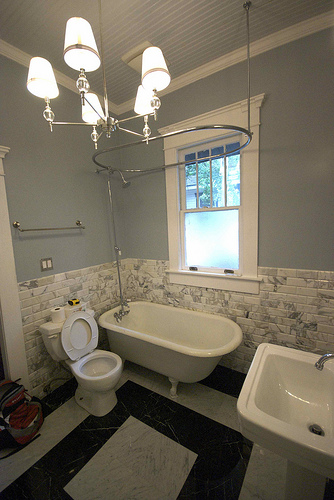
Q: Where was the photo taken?
A: It was taken at the bathroom.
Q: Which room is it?
A: It is a bathroom.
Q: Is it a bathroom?
A: Yes, it is a bathroom.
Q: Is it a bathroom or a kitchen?
A: It is a bathroom.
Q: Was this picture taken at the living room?
A: No, the picture was taken in the bathroom.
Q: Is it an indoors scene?
A: Yes, it is indoors.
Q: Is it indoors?
A: Yes, it is indoors.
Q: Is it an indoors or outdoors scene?
A: It is indoors.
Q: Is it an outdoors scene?
A: No, it is indoors.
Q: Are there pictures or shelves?
A: No, there are no shelves or pictures.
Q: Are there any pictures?
A: No, there are no pictures.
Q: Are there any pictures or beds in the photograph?
A: No, there are no pictures or beds.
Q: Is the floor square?
A: Yes, the floor is square.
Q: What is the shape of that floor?
A: The floor is square.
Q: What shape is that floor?
A: The floor is square.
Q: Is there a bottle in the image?
A: No, there are no bottles.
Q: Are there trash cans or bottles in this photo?
A: No, there are no bottles or trash cans.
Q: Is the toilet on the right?
A: No, the toilet is on the left of the image.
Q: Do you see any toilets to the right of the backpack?
A: Yes, there is a toilet to the right of the backpack.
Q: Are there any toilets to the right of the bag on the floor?
A: Yes, there is a toilet to the right of the backpack.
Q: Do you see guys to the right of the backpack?
A: No, there is a toilet to the right of the backpack.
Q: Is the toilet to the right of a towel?
A: No, the toilet is to the right of a backpack.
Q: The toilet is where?
A: The toilet is in the bathroom.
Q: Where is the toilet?
A: The toilet is in the bathroom.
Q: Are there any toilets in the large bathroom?
A: Yes, there is a toilet in the bathroom.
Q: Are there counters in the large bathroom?
A: No, there is a toilet in the bathroom.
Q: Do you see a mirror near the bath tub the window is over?
A: No, there is a toilet near the bath tub.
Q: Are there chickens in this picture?
A: No, there are no chickens.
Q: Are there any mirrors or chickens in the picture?
A: No, there are no chickens or mirrors.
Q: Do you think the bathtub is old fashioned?
A: Yes, the bathtub is old fashioned.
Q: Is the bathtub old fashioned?
A: Yes, the bathtub is old fashioned.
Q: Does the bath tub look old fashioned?
A: Yes, the bath tub is old fashioned.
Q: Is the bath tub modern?
A: No, the bath tub is old fashioned.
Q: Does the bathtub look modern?
A: No, the bathtub is old fashioned.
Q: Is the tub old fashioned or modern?
A: The tub is old fashioned.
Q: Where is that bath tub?
A: The bath tub is in the bathroom.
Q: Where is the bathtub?
A: The bath tub is in the bathroom.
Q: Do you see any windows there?
A: Yes, there is a window.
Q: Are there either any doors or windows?
A: Yes, there is a window.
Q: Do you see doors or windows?
A: Yes, there is a window.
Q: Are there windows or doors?
A: Yes, there is a window.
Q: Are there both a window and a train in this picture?
A: No, there is a window but no trains.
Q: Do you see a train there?
A: No, there are no trains.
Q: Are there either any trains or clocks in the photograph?
A: No, there are no trains or clocks.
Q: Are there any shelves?
A: No, there are no shelves.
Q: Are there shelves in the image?
A: No, there are no shelves.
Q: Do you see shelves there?
A: No, there are no shelves.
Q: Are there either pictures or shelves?
A: No, there are no shelves or pictures.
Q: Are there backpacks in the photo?
A: Yes, there is a backpack.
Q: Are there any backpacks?
A: Yes, there is a backpack.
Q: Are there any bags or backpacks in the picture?
A: Yes, there is a backpack.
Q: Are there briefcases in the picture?
A: No, there are no briefcases.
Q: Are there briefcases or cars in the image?
A: No, there are no briefcases or cars.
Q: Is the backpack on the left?
A: Yes, the backpack is on the left of the image.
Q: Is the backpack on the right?
A: No, the backpack is on the left of the image.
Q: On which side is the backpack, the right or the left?
A: The backpack is on the left of the image.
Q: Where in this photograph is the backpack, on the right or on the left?
A: The backpack is on the left of the image.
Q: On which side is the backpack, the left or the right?
A: The backpack is on the left of the image.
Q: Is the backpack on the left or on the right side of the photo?
A: The backpack is on the left of the image.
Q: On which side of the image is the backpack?
A: The backpack is on the left of the image.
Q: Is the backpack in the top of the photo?
A: No, the backpack is in the bottom of the image.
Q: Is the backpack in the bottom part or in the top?
A: The backpack is in the bottom of the image.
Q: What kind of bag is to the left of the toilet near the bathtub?
A: The bag is a backpack.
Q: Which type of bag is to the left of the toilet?
A: The bag is a backpack.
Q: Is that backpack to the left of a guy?
A: No, the backpack is to the left of a toilet.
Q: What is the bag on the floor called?
A: The bag is a backpack.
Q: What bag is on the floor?
A: The bag is a backpack.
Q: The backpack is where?
A: The backpack is on the floor.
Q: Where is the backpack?
A: The backpack is on the floor.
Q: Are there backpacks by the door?
A: Yes, there is a backpack by the door.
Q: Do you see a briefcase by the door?
A: No, there is a backpack by the door.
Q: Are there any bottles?
A: No, there are no bottles.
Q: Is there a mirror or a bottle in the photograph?
A: No, there are no bottles or mirrors.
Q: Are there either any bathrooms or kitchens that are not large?
A: No, there is a bathroom but it is large.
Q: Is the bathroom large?
A: Yes, the bathroom is large.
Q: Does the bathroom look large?
A: Yes, the bathroom is large.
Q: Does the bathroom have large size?
A: Yes, the bathroom is large.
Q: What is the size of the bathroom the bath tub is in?
A: The bathroom is large.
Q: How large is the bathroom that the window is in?
A: The bathroom is large.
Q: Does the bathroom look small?
A: No, the bathroom is large.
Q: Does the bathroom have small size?
A: No, the bathroom is large.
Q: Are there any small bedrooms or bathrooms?
A: No, there is a bathroom but it is large.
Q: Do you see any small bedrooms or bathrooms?
A: No, there is a bathroom but it is large.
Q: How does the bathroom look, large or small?
A: The bathroom is large.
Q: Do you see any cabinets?
A: No, there are no cabinets.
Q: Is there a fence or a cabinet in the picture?
A: No, there are no cabinets or fences.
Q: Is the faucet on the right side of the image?
A: Yes, the faucet is on the right of the image.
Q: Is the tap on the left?
A: No, the tap is on the right of the image.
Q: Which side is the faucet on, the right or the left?
A: The faucet is on the right of the image.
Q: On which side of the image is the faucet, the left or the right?
A: The faucet is on the right of the image.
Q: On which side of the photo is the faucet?
A: The faucet is on the right of the image.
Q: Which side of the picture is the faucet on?
A: The faucet is on the right of the image.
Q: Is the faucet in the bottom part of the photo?
A: Yes, the faucet is in the bottom of the image.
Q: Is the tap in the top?
A: No, the tap is in the bottom of the image.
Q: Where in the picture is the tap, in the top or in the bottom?
A: The tap is in the bottom of the image.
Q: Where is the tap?
A: The tap is in the bathroom.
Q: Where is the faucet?
A: The tap is in the bathroom.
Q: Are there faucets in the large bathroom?
A: Yes, there is a faucet in the bathroom.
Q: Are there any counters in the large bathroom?
A: No, there is a faucet in the bathroom.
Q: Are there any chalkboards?
A: No, there are no chalkboards.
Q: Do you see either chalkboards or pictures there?
A: No, there are no chalkboards or pictures.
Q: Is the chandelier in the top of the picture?
A: Yes, the chandelier is in the top of the image.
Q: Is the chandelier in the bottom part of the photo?
A: No, the chandelier is in the top of the image.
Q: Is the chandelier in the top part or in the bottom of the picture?
A: The chandelier is in the top of the image.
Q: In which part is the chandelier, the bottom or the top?
A: The chandelier is in the top of the image.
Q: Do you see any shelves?
A: No, there are no shelves.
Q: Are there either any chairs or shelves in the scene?
A: No, there are no shelves or chairs.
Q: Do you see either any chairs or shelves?
A: No, there are no shelves or chairs.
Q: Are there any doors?
A: Yes, there is a door.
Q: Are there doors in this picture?
A: Yes, there is a door.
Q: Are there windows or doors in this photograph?
A: Yes, there is a door.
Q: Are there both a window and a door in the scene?
A: Yes, there are both a door and a window.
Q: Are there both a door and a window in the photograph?
A: Yes, there are both a door and a window.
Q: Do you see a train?
A: No, there are no trains.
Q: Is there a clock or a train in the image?
A: No, there are no trains or clocks.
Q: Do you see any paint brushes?
A: No, there are no paint brushes.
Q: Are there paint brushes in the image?
A: No, there are no paint brushes.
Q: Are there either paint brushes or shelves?
A: No, there are no paint brushes or shelves.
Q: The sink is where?
A: The sink is in the bathroom.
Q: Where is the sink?
A: The sink is in the bathroom.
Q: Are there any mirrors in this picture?
A: No, there are no mirrors.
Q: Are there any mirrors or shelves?
A: No, there are no mirrors or shelves.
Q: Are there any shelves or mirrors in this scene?
A: No, there are no mirrors or shelves.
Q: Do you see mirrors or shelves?
A: No, there are no mirrors or shelves.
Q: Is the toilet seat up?
A: Yes, the toilet seat is up.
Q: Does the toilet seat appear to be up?
A: Yes, the toilet seat is up.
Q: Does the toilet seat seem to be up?
A: Yes, the toilet seat is up.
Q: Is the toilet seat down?
A: No, the toilet seat is up.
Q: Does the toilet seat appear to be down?
A: No, the toilet seat is up.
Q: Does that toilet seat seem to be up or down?
A: The toilet seat is up.